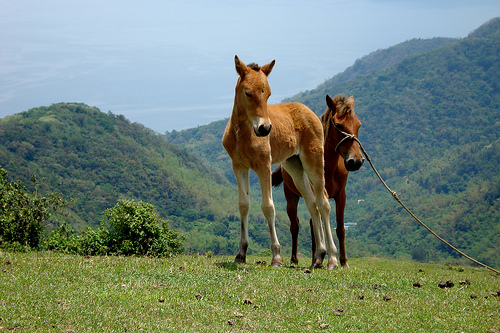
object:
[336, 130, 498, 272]
rope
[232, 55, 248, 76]
ears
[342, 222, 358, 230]
building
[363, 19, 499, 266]
hill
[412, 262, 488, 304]
dirt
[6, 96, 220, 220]
mountain side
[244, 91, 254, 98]
eyes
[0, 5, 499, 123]
sky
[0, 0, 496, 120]
clouds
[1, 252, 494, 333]
field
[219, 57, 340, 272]
colt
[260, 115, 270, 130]
snout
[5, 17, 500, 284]
range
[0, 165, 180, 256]
bushes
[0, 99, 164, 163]
hilltop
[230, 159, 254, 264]
leg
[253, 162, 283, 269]
leg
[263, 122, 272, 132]
nose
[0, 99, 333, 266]
hills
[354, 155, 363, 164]
nose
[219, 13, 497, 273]
forest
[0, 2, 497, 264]
mountain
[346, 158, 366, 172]
mouth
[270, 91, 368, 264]
horse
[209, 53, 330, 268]
horse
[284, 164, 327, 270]
leg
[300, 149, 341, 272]
leg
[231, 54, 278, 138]
head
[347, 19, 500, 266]
trees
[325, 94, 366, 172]
head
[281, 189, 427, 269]
valley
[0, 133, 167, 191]
trees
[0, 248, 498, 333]
grass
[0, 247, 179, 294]
cliffside